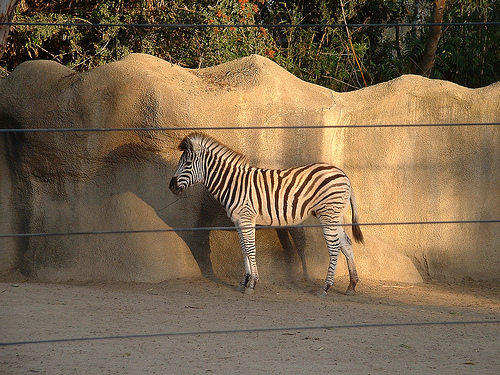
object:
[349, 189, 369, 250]
zebra tail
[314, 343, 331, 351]
leaves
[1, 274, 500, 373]
ground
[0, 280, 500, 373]
dirt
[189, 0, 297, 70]
trees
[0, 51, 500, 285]
wall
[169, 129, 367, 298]
zebra